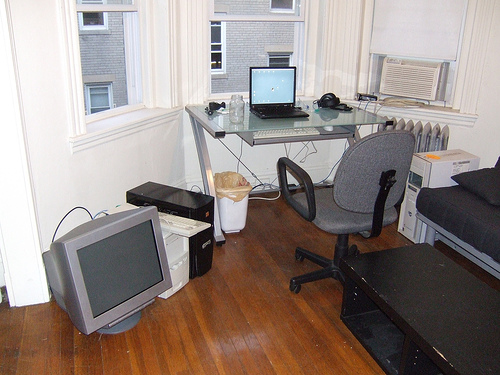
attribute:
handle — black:
[275, 156, 316, 225]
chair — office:
[272, 126, 427, 304]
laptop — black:
[245, 62, 312, 122]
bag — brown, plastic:
[213, 171, 253, 203]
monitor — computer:
[41, 203, 172, 335]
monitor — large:
[35, 205, 177, 339]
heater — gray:
[346, 41, 470, 159]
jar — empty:
[227, 94, 245, 124]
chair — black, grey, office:
[275, 130, 416, 291]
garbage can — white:
[214, 167, 251, 239]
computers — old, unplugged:
[127, 171, 221, 305]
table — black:
[335, 242, 499, 373]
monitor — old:
[50, 210, 165, 330]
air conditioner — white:
[378, 59, 448, 102]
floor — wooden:
[0, 180, 410, 371]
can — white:
[211, 167, 253, 239]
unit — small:
[374, 51, 449, 104]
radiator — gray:
[375, 116, 451, 159]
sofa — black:
[393, 158, 498, 239]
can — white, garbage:
[211, 161, 258, 232]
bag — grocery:
[213, 167, 251, 191]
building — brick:
[89, 25, 126, 98]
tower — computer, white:
[402, 121, 494, 284]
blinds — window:
[361, 7, 473, 95]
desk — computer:
[178, 93, 397, 243]